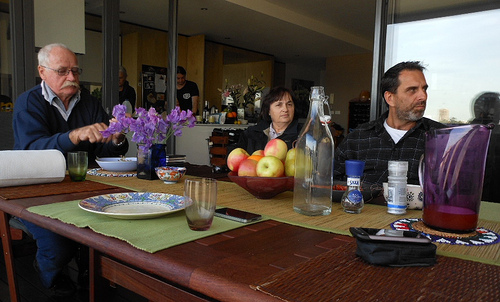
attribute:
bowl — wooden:
[228, 177, 292, 198]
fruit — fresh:
[230, 138, 295, 176]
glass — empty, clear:
[185, 180, 216, 230]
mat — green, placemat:
[97, 218, 189, 256]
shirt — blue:
[48, 90, 59, 105]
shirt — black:
[241, 124, 265, 149]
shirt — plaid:
[350, 127, 384, 161]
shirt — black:
[179, 81, 201, 107]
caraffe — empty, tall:
[293, 85, 334, 221]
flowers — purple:
[109, 106, 194, 142]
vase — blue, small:
[138, 146, 165, 170]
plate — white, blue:
[106, 201, 173, 217]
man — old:
[13, 42, 110, 151]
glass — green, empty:
[66, 151, 89, 181]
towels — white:
[0, 148, 67, 186]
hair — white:
[37, 45, 52, 66]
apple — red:
[231, 158, 248, 170]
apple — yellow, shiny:
[259, 157, 279, 179]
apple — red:
[265, 140, 274, 150]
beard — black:
[396, 110, 407, 117]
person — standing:
[178, 66, 202, 112]